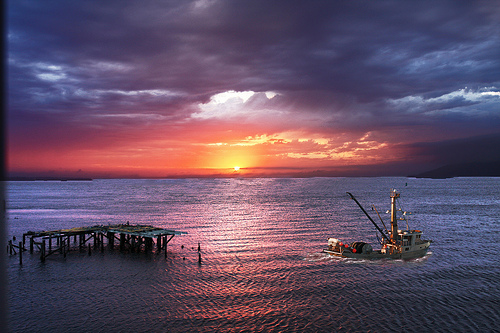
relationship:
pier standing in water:
[9, 218, 184, 275] [9, 177, 499, 331]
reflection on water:
[144, 175, 354, 329] [235, 195, 300, 245]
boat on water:
[312, 185, 437, 262] [9, 177, 499, 331]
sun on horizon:
[233, 165, 240, 171] [2, 174, 499, 179]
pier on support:
[9, 218, 184, 275] [26, 233, 168, 252]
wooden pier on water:
[18, 222, 187, 274] [15, 157, 451, 312]